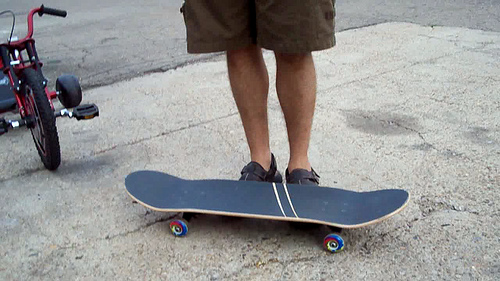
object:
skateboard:
[122, 168, 412, 255]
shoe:
[281, 164, 326, 187]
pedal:
[71, 101, 100, 122]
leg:
[178, 1, 271, 160]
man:
[177, 0, 339, 186]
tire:
[11, 64, 68, 173]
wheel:
[165, 220, 191, 236]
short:
[179, 1, 340, 55]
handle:
[39, 4, 70, 20]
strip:
[271, 181, 289, 217]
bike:
[0, 4, 101, 173]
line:
[281, 181, 303, 219]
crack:
[361, 115, 438, 149]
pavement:
[0, 0, 500, 280]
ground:
[0, 0, 500, 280]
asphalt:
[0, 0, 197, 100]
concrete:
[362, 97, 451, 134]